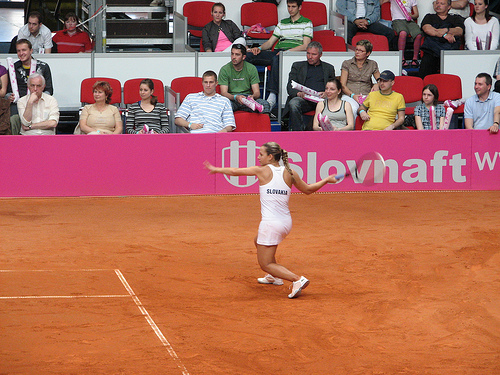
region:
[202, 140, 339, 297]
Woman swinging tennis racket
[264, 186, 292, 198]
SLOVAKIA printed on white shirt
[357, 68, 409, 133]
Man wearing blue hat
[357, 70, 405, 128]
Man wearing yellow shirt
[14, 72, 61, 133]
Man placing hand on lip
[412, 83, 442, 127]
Young girl sitting next to man wearing yellow shirt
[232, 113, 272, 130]
Empty red seat next to man in blue and white striped shirt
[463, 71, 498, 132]
Man wearing light blue polo shirt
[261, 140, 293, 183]
Hair is in a braid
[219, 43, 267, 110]
Man wearing green shirt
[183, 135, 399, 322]
the woman playing tennis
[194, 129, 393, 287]
the woman swinging a tennis racket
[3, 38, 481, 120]
spectators watching tennis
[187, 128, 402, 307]
the woman on the court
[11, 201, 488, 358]
the court is clay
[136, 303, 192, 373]
the line is painted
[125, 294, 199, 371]
the line is white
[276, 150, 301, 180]
the ponytail of the woman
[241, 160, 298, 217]
the woman wearing white top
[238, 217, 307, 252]
the woman wearing white shorts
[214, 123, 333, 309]
woman wearing a white tennis suit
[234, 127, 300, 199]
woman with braided hair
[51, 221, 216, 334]
orange clay tennis court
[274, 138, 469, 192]
slovnaft logo on a pink tennis wall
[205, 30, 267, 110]
man wearing a green t-shirt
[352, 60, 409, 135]
man wearing a yellow t-shirt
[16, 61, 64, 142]
elderly man wearing a long sleeved shirt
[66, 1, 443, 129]
spectators at a tennis match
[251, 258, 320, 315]
white tennis shoes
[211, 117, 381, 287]
woman swinging a tennis racquet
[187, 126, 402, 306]
Woman is playing tennis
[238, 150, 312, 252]
Woman is wearing a white sports dress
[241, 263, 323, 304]
Woman is wearing white tennis shoes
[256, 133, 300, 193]
Woman has dirty blonde hair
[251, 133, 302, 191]
Woman's hair is in a pony tail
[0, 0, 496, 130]
A crowd of people in the background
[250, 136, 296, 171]
A side view of the woman's head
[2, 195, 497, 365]
Ground is made up of dirt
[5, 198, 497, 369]
Dirt is orange colored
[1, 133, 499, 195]
A pink advertisement sign in the background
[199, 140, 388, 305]
Girl swinging tennis racket.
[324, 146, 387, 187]
Tennis racket being swung.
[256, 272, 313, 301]
White tennis shoes being worn by woman.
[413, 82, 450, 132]
Young girl in plaid shirt.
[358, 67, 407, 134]
Man in yellow shirt.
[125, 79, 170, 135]
Woman in striped shirt.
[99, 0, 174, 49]
Stairs to more seats.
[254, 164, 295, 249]
White tennis dress with black text.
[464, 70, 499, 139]
Man with grey shirt.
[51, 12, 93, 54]
Woman in red shirt.